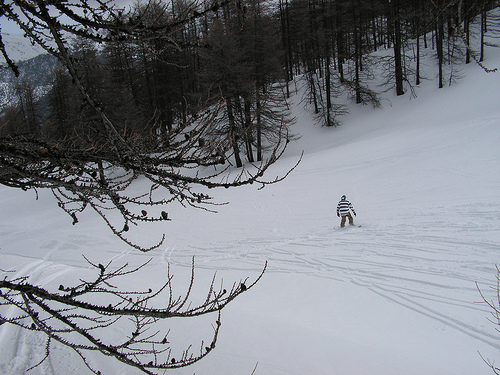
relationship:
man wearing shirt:
[336, 195, 356, 227] [336, 200, 356, 215]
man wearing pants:
[336, 195, 356, 227] [339, 213, 357, 228]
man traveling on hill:
[336, 195, 357, 230] [160, 6, 497, 367]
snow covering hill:
[31, 36, 495, 347] [13, 0, 492, 141]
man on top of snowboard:
[336, 195, 356, 227] [318, 215, 428, 257]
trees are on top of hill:
[5, 2, 499, 176] [4, 10, 495, 182]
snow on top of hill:
[15, 22, 177, 148] [0, 0, 497, 375]